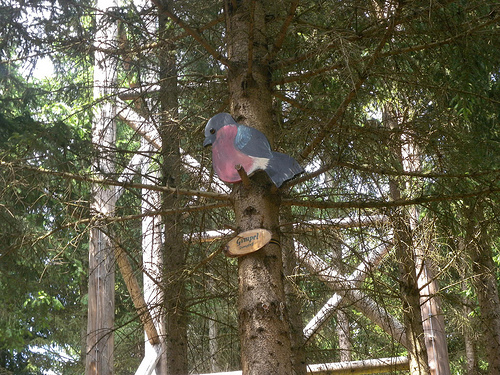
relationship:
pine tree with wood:
[112, 0, 397, 372] [199, 110, 308, 188]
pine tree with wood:
[112, 0, 397, 372] [220, 227, 281, 260]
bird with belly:
[203, 112, 300, 186] [208, 139, 256, 183]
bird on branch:
[203, 112, 300, 186] [231, 160, 255, 195]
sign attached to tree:
[221, 228, 278, 257] [218, 0, 310, 371]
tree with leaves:
[3, 2, 98, 372] [0, 239, 69, 320]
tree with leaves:
[1, 182, 142, 372] [17, 282, 67, 327]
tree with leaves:
[191, 68, 302, 349] [155, 13, 213, 75]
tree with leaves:
[283, 7, 481, 373] [421, 38, 484, 83]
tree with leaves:
[268, 6, 468, 373] [370, 269, 410, 309]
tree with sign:
[218, 0, 310, 371] [222, 227, 276, 256]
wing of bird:
[229, 123, 272, 157] [203, 112, 300, 186]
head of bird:
[200, 110, 240, 150] [203, 112, 300, 186]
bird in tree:
[203, 112, 300, 186] [192, 16, 322, 344]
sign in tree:
[221, 228, 274, 257] [181, 22, 306, 341]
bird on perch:
[203, 112, 300, 186] [232, 164, 257, 191]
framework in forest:
[89, 60, 449, 337] [45, 38, 473, 351]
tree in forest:
[191, 68, 302, 349] [23, 43, 480, 364]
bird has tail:
[203, 112, 300, 186] [266, 150, 300, 188]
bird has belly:
[203, 112, 300, 186] [210, 137, 260, 177]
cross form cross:
[296, 238, 407, 344] [296, 238, 407, 344]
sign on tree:
[221, 228, 274, 257] [220, 159, 300, 332]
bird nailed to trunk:
[197, 108, 299, 186] [214, 127, 292, 263]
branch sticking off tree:
[78, 199, 200, 220] [205, 79, 311, 333]